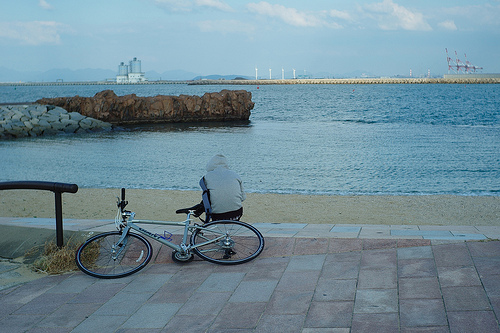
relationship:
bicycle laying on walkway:
[88, 186, 204, 286] [284, 243, 405, 302]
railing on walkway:
[2, 175, 80, 195] [284, 243, 405, 302]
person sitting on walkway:
[200, 145, 248, 220] [284, 243, 405, 302]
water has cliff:
[309, 120, 381, 160] [81, 92, 236, 118]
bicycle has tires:
[88, 186, 204, 286] [195, 221, 266, 266]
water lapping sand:
[62, 89, 256, 128] [290, 194, 388, 217]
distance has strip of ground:
[315, 66, 361, 84] [0, 183, 500, 333]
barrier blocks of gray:
[15, 108, 56, 129] [6, 109, 28, 123]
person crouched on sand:
[200, 145, 248, 220] [290, 194, 388, 217]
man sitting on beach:
[200, 145, 248, 220] [268, 184, 406, 227]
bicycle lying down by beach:
[88, 186, 204, 286] [268, 184, 406, 227]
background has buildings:
[196, 25, 245, 42] [114, 56, 147, 67]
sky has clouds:
[241, 20, 301, 48] [299, 12, 367, 28]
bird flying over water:
[236, 43, 261, 54] [62, 89, 256, 128]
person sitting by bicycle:
[200, 145, 248, 220] [88, 186, 204, 286]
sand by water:
[290, 194, 388, 217] [62, 89, 256, 128]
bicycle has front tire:
[88, 186, 204, 286] [73, 228, 153, 279]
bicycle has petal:
[88, 186, 204, 286] [178, 241, 191, 256]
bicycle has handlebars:
[88, 186, 204, 286] [115, 181, 132, 216]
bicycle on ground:
[88, 186, 204, 286] [290, 246, 360, 280]